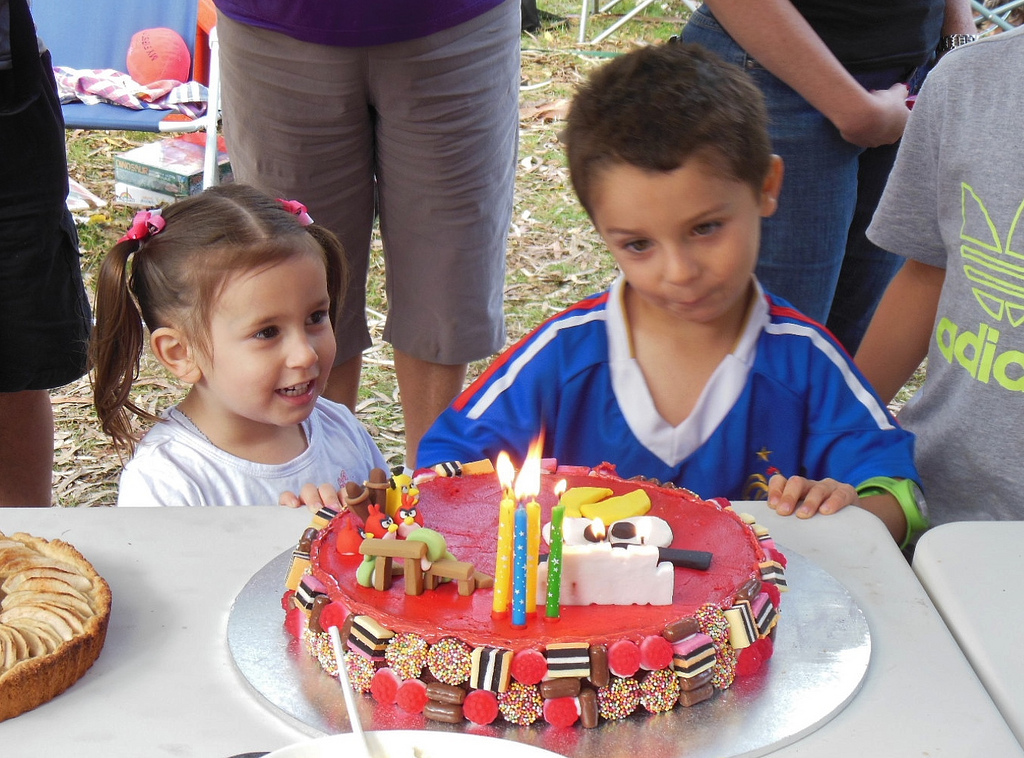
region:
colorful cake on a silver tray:
[220, 437, 879, 752]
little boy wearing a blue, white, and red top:
[408, 41, 934, 545]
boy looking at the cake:
[287, 38, 939, 735]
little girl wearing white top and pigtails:
[81, 180, 392, 507]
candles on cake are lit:
[268, 429, 794, 730]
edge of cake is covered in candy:
[281, 443, 790, 726]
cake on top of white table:
[2, 445, 1023, 756]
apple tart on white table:
[0, 499, 1023, 756]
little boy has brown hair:
[420, 40, 930, 552]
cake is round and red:
[269, 435, 788, 739]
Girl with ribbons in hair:
[100, 180, 396, 506]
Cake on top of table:
[5, 449, 1021, 756]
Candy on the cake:
[284, 453, 791, 726]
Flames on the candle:
[485, 433, 566, 629]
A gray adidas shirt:
[861, 25, 1021, 534]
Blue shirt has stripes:
[403, 279, 923, 555]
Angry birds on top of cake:
[280, 443, 783, 725]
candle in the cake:
[531, 499, 582, 611]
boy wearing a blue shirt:
[438, 275, 904, 510]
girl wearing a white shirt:
[129, 386, 399, 511]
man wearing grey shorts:
[208, 6, 513, 395]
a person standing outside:
[558, 83, 844, 533]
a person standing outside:
[169, 203, 414, 501]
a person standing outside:
[860, 66, 1020, 361]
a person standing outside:
[661, 7, 930, 372]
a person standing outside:
[184, 31, 649, 522]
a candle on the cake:
[555, 446, 607, 571]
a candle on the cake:
[500, 434, 538, 591]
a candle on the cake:
[512, 446, 585, 627]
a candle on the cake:
[473, 437, 625, 738]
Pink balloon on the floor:
[118, 22, 194, 95]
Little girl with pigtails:
[83, 170, 394, 513]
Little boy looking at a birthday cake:
[405, 28, 940, 547]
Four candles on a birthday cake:
[482, 421, 568, 630]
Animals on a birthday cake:
[348, 502, 482, 604]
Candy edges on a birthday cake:
[288, 569, 772, 737]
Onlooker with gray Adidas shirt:
[854, 21, 1016, 518]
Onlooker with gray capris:
[212, 4, 514, 482]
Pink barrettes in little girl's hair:
[111, 196, 326, 250]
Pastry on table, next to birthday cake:
[1, 525, 113, 734]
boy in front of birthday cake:
[365, 47, 960, 539]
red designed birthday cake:
[263, 449, 785, 729]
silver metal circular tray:
[213, 455, 871, 756]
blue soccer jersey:
[408, 266, 921, 507]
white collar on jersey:
[590, 263, 787, 456]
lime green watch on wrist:
[844, 446, 922, 532]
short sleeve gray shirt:
[861, 16, 1021, 523]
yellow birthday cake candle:
[490, 487, 519, 617]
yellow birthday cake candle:
[523, 500, 543, 609]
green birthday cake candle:
[539, 506, 572, 615]